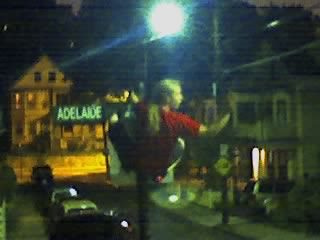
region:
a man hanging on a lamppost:
[114, 16, 249, 186]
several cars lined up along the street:
[31, 169, 130, 237]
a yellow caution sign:
[210, 150, 235, 179]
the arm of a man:
[185, 108, 247, 151]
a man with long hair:
[145, 76, 186, 140]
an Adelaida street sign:
[51, 103, 108, 121]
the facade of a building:
[8, 51, 103, 161]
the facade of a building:
[190, 78, 319, 226]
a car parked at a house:
[241, 174, 290, 218]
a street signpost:
[56, 16, 151, 238]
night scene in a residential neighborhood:
[0, 0, 314, 234]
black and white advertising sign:
[51, 103, 107, 122]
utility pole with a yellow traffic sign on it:
[210, 0, 235, 226]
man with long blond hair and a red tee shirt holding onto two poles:
[106, 75, 233, 188]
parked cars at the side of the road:
[236, 166, 314, 229]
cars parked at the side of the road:
[25, 163, 134, 235]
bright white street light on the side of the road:
[137, 0, 195, 46]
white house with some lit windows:
[7, 50, 76, 153]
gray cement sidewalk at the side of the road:
[151, 176, 311, 237]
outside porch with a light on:
[230, 140, 294, 193]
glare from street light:
[148, 1, 190, 37]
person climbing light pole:
[103, 70, 232, 191]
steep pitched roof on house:
[9, 47, 80, 88]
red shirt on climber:
[132, 99, 200, 167]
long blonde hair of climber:
[147, 79, 182, 133]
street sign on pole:
[210, 154, 233, 177]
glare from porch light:
[249, 143, 267, 185]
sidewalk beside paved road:
[235, 217, 300, 239]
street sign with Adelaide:
[53, 106, 110, 122]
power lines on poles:
[215, 35, 319, 80]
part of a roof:
[306, 142, 316, 152]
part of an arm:
[176, 119, 182, 128]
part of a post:
[104, 123, 113, 135]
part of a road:
[193, 205, 201, 213]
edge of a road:
[164, 177, 179, 198]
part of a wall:
[254, 136, 256, 148]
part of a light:
[254, 162, 261, 180]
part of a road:
[199, 203, 206, 215]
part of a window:
[39, 106, 47, 116]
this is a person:
[100, 82, 234, 187]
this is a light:
[131, 3, 201, 53]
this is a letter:
[54, 102, 65, 127]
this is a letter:
[62, 101, 71, 123]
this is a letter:
[69, 102, 75, 123]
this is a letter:
[73, 106, 81, 126]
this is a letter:
[80, 104, 89, 124]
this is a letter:
[85, 105, 90, 120]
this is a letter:
[95, 104, 106, 127]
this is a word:
[56, 100, 111, 131]